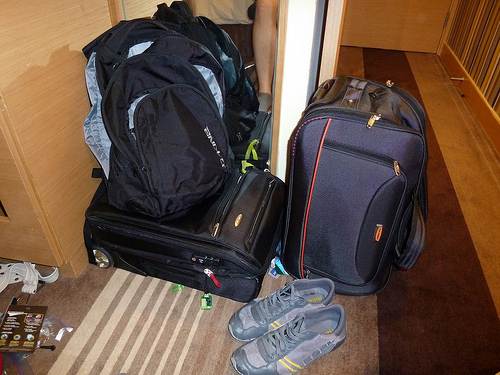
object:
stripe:
[294, 119, 335, 283]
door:
[342, 7, 446, 57]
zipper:
[394, 161, 401, 177]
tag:
[245, 139, 259, 160]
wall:
[456, 2, 497, 59]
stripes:
[462, 19, 492, 59]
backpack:
[276, 76, 429, 298]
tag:
[200, 291, 213, 310]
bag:
[81, 152, 288, 303]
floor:
[69, 278, 231, 372]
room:
[0, 2, 496, 372]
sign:
[203, 126, 227, 168]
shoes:
[228, 278, 334, 349]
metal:
[451, 70, 467, 85]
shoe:
[231, 304, 347, 374]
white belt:
[0, 263, 59, 295]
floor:
[301, 35, 498, 152]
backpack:
[84, 17, 236, 223]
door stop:
[450, 77, 464, 81]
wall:
[471, 78, 500, 127]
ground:
[9, 46, 498, 373]